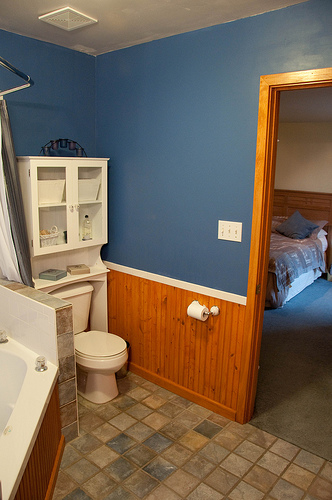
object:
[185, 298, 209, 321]
toilet paper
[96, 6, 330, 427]
wall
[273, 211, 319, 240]
pillow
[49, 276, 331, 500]
floor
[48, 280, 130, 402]
toilet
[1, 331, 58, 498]
bathtub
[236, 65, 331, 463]
doorway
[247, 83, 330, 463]
bedroom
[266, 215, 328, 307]
bedspread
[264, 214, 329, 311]
bed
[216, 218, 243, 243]
light switch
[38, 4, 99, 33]
ceiling vent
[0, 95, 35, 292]
shower curtain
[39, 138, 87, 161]
design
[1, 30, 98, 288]
wall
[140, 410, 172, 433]
stone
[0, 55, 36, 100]
hanger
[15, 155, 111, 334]
cupboard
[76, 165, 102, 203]
window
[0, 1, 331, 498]
bathroom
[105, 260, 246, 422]
boarding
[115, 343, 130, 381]
trash bin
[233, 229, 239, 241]
switch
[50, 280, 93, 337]
toilet sink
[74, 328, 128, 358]
lid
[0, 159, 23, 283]
screen